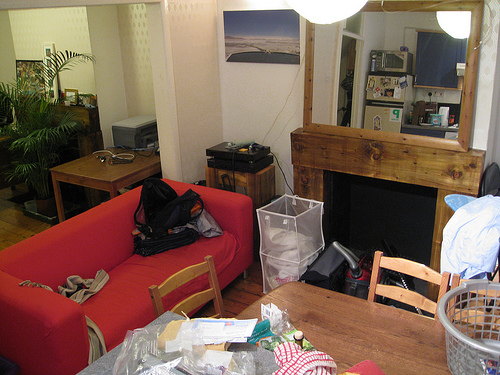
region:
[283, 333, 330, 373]
red and white wash cloth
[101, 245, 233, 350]
a brown wooden cahir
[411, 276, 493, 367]
a gray laundry basket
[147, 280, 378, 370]
clutter on a table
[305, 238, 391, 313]
a rev and gray vacume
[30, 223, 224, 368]
a revd couch with stuff on it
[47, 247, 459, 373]
two wooden chairs with two slats each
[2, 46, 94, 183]
a bushy greeen plant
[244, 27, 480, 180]
a mirror with a reflection in it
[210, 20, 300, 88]
a picture on the wall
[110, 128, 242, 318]
the couch is red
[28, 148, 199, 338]
the couch is red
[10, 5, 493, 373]
A living room scene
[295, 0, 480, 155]
A mirror is on the wall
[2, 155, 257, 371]
A red couch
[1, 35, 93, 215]
A plant is in the corner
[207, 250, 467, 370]
This is a table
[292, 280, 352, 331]
The table is made of wood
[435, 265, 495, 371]
A clothes basket is on the table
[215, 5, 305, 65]
A picture is on the wall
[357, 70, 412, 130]
A refrigerator is reflected in the mirror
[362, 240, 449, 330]
A chair is by the table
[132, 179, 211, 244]
Black backpack on red sofa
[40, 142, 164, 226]
Brown table behind red sofa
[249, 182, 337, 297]
White hamper by fireplace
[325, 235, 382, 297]
Vacuum behind wooden chair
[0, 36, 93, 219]
Big green plant behind table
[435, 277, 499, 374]
Gray basket on wooden table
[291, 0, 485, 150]
Mirror next to hung picture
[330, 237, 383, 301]
Vacuum next to white hamper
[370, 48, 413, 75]
Reflection of microwave oven in mirror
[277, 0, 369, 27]
Light above table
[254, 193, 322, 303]
white hamper beside fireplace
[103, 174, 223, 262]
black clothes on sofa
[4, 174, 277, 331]
sofa is red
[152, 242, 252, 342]
brown chair next to table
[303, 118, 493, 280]
fireplace has wooden frame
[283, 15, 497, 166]
window over fireplace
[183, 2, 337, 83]
landscape picture next to fireplace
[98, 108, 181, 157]
printer on table is grey and white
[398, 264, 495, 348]
grey basket on table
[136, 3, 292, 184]
wall is off white